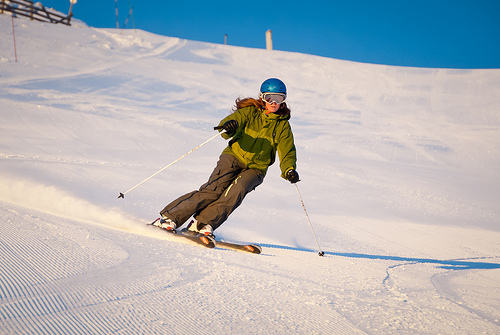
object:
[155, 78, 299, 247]
woman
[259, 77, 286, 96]
helmet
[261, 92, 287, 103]
goggles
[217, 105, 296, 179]
jacket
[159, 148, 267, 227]
pants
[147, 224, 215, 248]
skis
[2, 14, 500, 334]
snow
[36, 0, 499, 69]
sky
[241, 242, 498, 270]
shadow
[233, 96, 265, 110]
hair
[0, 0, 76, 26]
fence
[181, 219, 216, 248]
boots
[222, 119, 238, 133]
glove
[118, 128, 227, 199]
ski pole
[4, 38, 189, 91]
tracks